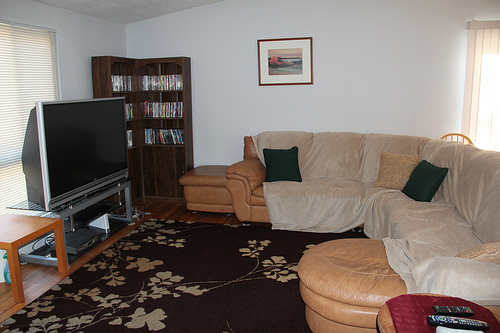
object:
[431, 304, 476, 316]
remote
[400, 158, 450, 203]
pillow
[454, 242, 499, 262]
pillow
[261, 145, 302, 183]
pillow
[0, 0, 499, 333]
living room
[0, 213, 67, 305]
brown table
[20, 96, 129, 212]
television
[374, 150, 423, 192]
pillow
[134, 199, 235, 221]
ground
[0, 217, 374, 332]
carpet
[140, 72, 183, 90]
books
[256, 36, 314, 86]
picture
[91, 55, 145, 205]
bookcase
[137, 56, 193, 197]
bookcase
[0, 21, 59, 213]
blinds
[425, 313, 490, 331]
remotes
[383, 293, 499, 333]
cloth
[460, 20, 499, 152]
curtain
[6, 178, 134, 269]
stand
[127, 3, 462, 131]
wall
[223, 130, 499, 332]
couch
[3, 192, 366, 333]
floor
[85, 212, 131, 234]
console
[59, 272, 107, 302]
floral pattern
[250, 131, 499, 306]
sheet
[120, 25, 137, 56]
corner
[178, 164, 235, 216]
footrest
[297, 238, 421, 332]
footrest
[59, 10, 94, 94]
wall